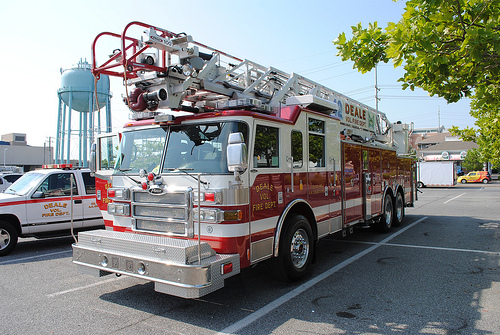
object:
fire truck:
[68, 19, 422, 302]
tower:
[56, 58, 113, 168]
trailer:
[417, 159, 458, 189]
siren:
[42, 163, 73, 169]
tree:
[332, 2, 500, 173]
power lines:
[340, 85, 402, 96]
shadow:
[99, 215, 499, 335]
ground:
[0, 179, 498, 334]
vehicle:
[0, 164, 107, 257]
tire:
[264, 209, 318, 284]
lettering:
[252, 204, 256, 212]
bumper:
[65, 227, 241, 300]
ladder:
[90, 20, 396, 143]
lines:
[212, 217, 427, 335]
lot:
[0, 185, 497, 335]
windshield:
[111, 123, 246, 174]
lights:
[201, 209, 221, 225]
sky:
[0, 0, 499, 138]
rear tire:
[368, 191, 396, 234]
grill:
[129, 187, 192, 238]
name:
[251, 182, 279, 213]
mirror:
[227, 132, 248, 174]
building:
[416, 140, 495, 177]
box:
[77, 229, 217, 265]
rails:
[89, 20, 168, 82]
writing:
[344, 102, 350, 115]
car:
[456, 170, 491, 185]